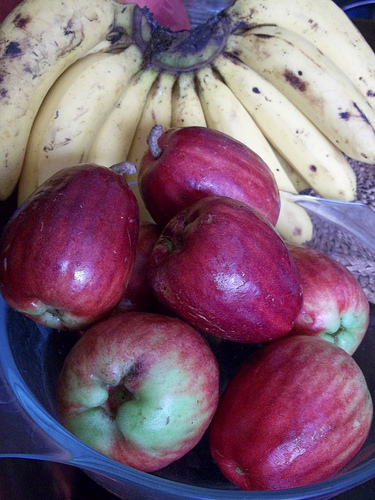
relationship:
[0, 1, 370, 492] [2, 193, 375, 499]
fruit in a bowl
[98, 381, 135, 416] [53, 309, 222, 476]
hole in fruit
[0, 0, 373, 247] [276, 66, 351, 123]
bananas has brown parts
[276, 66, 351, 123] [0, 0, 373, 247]
brown parts are on bananas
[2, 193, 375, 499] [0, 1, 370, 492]
bowl of fruit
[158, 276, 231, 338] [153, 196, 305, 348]
marks are on side of apple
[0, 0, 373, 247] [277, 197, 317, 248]
bananas has a tip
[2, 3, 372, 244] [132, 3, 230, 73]
bananas are fanning from stem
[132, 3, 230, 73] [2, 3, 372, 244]
ring around edge of bananas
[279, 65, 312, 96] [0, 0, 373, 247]
dark spots are on bananas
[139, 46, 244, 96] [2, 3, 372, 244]
dark spaces are between bananas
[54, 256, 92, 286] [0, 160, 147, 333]
light reflecting off fruit